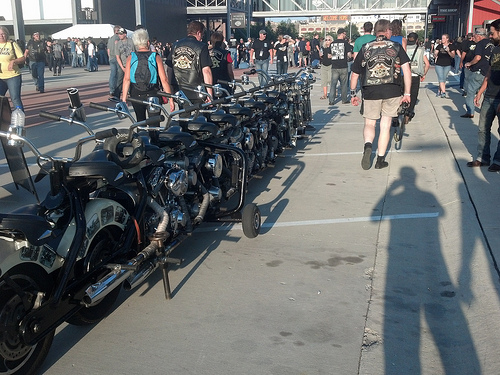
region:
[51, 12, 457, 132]
many people in photo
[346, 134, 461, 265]
shadow on the ground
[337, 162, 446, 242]
shadow of a man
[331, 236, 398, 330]
line on the ground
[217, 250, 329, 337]
gray pavement in photo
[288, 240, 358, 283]
marks on the pavement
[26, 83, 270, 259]
bikes next to people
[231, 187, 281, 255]
wheel on the ground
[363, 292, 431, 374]
shadow of a leg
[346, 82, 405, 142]
shorts on the man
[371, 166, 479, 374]
photographer's shadow stretches long across sidewalk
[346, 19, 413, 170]
man in khaki shorts and black biker vest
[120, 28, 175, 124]
woman with silver hair wearing vest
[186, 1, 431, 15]
metal and glass walkway across roadway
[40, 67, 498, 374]
long concrete sidewalk with oil stains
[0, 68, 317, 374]
long row of tightly positioned motorcycles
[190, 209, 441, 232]
white line painted on sidewalk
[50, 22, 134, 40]
white tent on opposite side of road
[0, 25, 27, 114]
woman wearing yellow t-shirt and blue jeans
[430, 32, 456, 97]
woman wearing black t-shirt and capris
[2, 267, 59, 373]
the wheel of a motorcycle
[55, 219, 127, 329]
the wheel of a motorcycle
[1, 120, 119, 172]
the handles of a motorcycle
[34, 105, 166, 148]
the handles of a motorcycle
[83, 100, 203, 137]
the handles of a motorcycle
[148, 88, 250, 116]
the handles of a motorcycle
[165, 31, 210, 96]
a man with a leather jacket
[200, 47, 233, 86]
a man with a leather jacket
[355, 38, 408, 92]
a man with a leather jacket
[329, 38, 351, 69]
a man with a black shirt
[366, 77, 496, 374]
shadows of people on the ground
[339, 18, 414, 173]
a man wears a leather bikers vest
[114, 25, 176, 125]
woman has short silver hair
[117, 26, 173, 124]
woman is wearing a blue and black backpack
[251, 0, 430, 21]
a walkway above a busy street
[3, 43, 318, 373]
motorcycles are lined up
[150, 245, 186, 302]
motorcycle kick stand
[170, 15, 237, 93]
two people wear matching bikers vests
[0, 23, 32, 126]
woman wears a yellow shirt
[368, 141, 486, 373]
this is a shadow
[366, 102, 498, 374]
these are the shadows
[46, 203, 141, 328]
this is a wheel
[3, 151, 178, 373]
these are the wheels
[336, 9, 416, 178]
this is the man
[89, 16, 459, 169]
these are the men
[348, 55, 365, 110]
this is an arm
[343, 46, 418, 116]
these are the arms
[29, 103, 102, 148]
this is a handle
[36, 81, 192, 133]
these are the handles